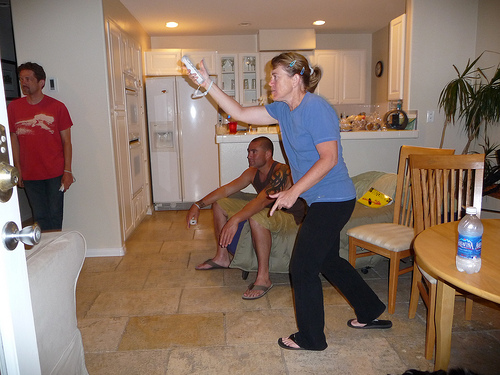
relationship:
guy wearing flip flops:
[185, 135, 293, 299] [192, 256, 277, 301]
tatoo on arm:
[264, 161, 293, 200] [213, 163, 288, 252]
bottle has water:
[448, 195, 497, 278] [466, 226, 474, 230]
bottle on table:
[448, 195, 497, 278] [417, 270, 484, 360]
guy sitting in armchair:
[185, 135, 293, 299] [213, 161, 406, 280]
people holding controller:
[180, 50, 395, 352] [179, 50, 215, 99]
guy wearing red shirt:
[7, 61, 75, 230] [9, 98, 66, 183]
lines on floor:
[172, 284, 190, 308] [81, 209, 498, 371]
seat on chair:
[351, 216, 419, 243] [352, 211, 416, 313]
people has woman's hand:
[180, 50, 395, 352] [171, 56, 242, 122]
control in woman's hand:
[180, 57, 206, 84] [171, 56, 242, 122]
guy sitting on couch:
[185, 135, 293, 299] [226, 170, 457, 275]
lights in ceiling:
[134, 21, 358, 82] [121, 3, 409, 32]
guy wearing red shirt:
[7, 61, 75, 230] [7, 93, 73, 181]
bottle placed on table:
[455, 206, 484, 273] [417, 217, 484, 369]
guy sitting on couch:
[192, 135, 280, 290] [189, 185, 423, 269]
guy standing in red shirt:
[4, 60, 72, 228] [7, 93, 73, 181]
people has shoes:
[180, 50, 395, 352] [194, 258, 229, 269]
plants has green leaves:
[432, 60, 497, 181] [451, 79, 491, 102]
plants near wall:
[432, 60, 497, 181] [398, 2, 495, 154]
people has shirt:
[180, 50, 395, 352] [254, 90, 362, 210]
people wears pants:
[180, 50, 395, 352] [259, 179, 420, 346]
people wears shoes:
[180, 50, 395, 352] [278, 304, 405, 359]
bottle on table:
[455, 206, 484, 273] [412, 204, 499, 374]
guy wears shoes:
[185, 135, 293, 299] [234, 267, 272, 304]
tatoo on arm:
[264, 161, 292, 195] [215, 158, 294, 249]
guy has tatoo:
[185, 135, 293, 299] [264, 161, 292, 195]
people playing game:
[180, 50, 395, 352] [180, 55, 215, 99]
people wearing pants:
[180, 50, 395, 352] [276, 189, 390, 352]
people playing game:
[165, 51, 423, 368] [176, 58, 218, 95]